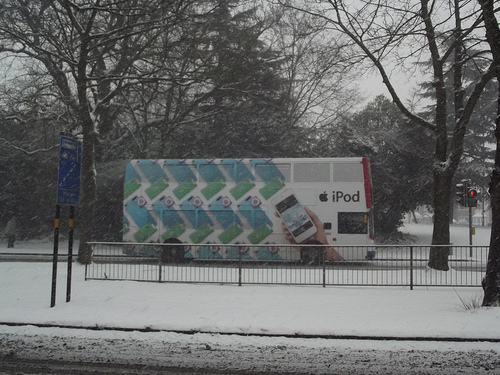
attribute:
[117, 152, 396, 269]
bus — advertising, parked, double decker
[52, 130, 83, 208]
sign — blue, white, crosswalk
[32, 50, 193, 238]
trees — tall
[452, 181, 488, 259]
traffic light — red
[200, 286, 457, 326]
snow — white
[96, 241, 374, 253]
railing — steel, metal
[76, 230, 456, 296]
fence — steel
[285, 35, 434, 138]
snow — falling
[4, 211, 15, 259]
man — walking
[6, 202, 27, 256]
person — walking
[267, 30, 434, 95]
sky — gloomy, grey, cloudy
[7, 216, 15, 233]
jacket — grey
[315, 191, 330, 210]
logo — apple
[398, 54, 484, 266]
tree — leafless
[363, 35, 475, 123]
branches — bare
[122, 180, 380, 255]
vehicle — colorful